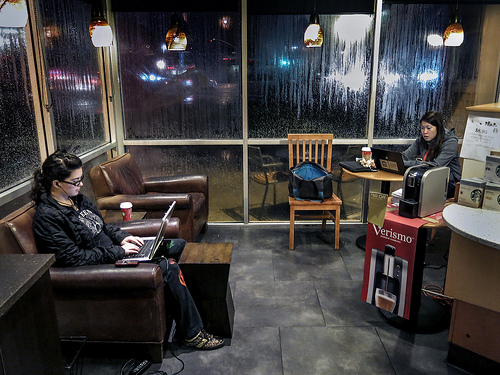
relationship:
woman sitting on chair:
[29, 149, 228, 349] [0, 163, 184, 373]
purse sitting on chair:
[280, 156, 330, 203] [287, 133, 342, 251]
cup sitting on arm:
[118, 200, 135, 221] [100, 203, 149, 224]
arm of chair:
[100, 203, 149, 224] [94, 156, 211, 222]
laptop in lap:
[110, 198, 182, 265] [104, 233, 184, 268]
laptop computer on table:
[367, 147, 413, 176] [339, 157, 402, 196]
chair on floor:
[287, 133, 342, 251] [200, 213, 373, 354]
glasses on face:
[59, 173, 85, 188] [48, 160, 88, 197]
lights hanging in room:
[89, 22, 114, 49] [7, 19, 469, 369]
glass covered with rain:
[381, 14, 444, 132] [380, 18, 421, 138]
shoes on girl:
[180, 331, 228, 348] [31, 151, 235, 351]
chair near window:
[96, 151, 211, 234] [42, 40, 238, 150]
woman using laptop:
[25, 139, 222, 358] [120, 197, 181, 264]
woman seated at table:
[399, 111, 462, 189] [340, 160, 402, 227]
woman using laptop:
[399, 111, 462, 189] [371, 131, 404, 174]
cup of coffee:
[118, 198, 138, 221] [360, 164, 438, 321]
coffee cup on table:
[360, 146, 373, 162] [339, 162, 400, 195]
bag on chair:
[288, 160, 340, 203] [276, 127, 346, 257]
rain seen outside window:
[4, 25, 417, 151] [1, 22, 368, 130]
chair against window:
[287, 133, 342, 251] [4, 23, 407, 130]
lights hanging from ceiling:
[0, 10, 497, 76] [2, 2, 497, 18]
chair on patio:
[246, 145, 281, 216] [208, 145, 362, 219]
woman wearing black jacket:
[29, 149, 228, 349] [19, 190, 159, 266]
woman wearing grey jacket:
[397, 106, 470, 206] [397, 123, 465, 185]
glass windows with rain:
[14, 10, 469, 220] [74, 27, 461, 144]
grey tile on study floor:
[74, 210, 466, 371] [65, 193, 497, 359]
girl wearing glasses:
[31, 151, 235, 351] [59, 178, 85, 186]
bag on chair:
[288, 160, 334, 202] [276, 127, 346, 257]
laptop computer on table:
[365, 148, 415, 174] [327, 150, 430, 253]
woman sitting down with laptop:
[25, 139, 222, 358] [112, 193, 182, 262]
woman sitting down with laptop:
[399, 111, 462, 189] [363, 139, 422, 180]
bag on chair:
[288, 160, 334, 202] [283, 125, 343, 248]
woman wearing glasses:
[25, 139, 222, 358] [59, 178, 85, 186]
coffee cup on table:
[355, 134, 384, 174] [340, 144, 422, 259]